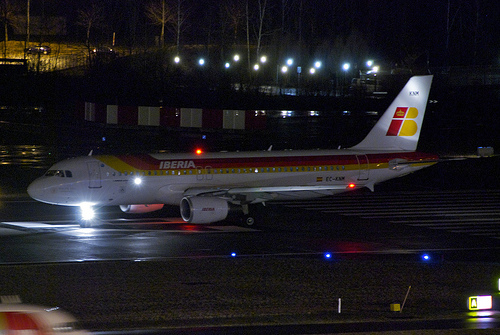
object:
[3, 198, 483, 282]
courtyard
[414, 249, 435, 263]
lights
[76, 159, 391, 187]
side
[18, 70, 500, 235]
jet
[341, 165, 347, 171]
windows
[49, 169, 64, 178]
pilot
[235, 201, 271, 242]
gear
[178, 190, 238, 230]
engine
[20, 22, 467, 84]
line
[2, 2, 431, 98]
trees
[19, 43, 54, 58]
car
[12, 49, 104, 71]
street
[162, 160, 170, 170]
b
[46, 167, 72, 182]
window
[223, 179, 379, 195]
wing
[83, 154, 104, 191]
door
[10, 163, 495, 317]
pavement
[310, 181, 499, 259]
lines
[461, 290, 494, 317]
box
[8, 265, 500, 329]
field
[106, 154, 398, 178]
stripes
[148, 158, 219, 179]
lettering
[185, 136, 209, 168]
light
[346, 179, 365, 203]
light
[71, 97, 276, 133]
building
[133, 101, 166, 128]
doors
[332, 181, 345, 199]
edge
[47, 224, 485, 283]
part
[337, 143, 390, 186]
part